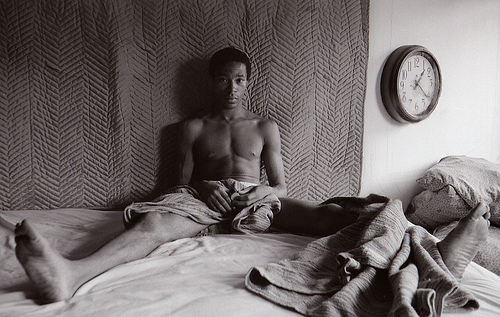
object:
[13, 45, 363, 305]
boy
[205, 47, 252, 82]
hair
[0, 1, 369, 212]
fabric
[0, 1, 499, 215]
wall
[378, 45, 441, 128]
clock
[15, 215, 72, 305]
right foot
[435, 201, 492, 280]
left foot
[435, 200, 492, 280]
foot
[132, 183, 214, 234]
lap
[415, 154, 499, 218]
pillow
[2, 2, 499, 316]
room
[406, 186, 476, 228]
pillow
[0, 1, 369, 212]
back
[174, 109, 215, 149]
right shoulder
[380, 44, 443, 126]
frame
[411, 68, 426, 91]
hand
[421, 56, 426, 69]
1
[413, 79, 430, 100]
hand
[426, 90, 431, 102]
4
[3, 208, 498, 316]
bed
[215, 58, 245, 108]
face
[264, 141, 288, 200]
arm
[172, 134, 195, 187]
arm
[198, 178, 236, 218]
hand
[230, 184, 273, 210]
hand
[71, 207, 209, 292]
leg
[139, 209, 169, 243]
knee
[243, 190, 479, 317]
blanket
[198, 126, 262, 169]
chest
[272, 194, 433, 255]
leg